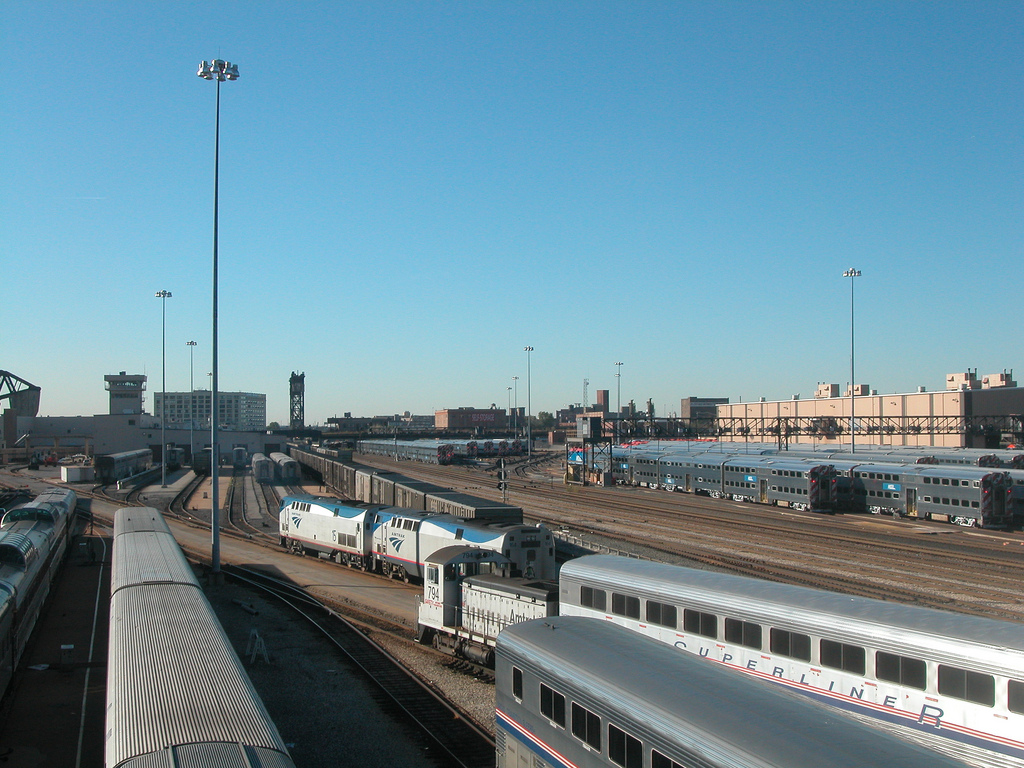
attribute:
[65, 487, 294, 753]
train — gray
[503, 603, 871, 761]
train — gray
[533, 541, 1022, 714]
train — gray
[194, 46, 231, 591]
pole — tall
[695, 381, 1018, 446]
building — beige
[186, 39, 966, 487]
sky — clear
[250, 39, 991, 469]
sky — blue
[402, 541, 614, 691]
engine — small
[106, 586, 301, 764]
train car — silver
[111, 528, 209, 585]
train car — silver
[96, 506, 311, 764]
train — passenger, silver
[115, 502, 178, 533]
train car — silver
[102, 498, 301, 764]
train — silver, passenger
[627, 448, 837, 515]
train — silver, passenger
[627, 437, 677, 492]
train car — silver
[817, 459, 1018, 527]
train — silver, passenger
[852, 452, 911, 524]
train car — silver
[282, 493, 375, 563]
train engine — white, blue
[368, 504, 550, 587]
train engine — white, blue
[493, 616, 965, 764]
train — gray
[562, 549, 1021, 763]
train — gray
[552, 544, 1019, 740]
train — gray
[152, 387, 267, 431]
building — multi-story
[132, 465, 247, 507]
tracks — empty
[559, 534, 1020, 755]
train — silver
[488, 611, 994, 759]
train — silver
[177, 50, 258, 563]
light pole — tall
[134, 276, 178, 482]
light pole — tall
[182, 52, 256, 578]
pole — tall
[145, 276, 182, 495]
light pole — tall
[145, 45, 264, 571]
light poles — tall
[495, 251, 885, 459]
light poles — tall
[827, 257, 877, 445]
light pole — tall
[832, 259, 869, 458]
pole — tall, light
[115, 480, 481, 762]
tracks — train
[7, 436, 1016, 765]
depot — train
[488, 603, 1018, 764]
car — train, gray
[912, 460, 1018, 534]
train car — gray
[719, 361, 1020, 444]
building — large, brown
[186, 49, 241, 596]
light post — silver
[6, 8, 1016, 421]
sky — blue